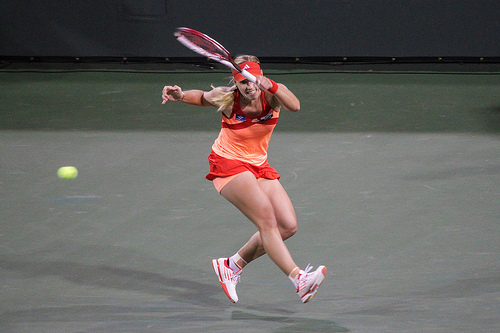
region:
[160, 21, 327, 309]
Woman in red playing tennis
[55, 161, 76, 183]
bright yellow tennis ball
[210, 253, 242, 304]
orange and white tennis shoes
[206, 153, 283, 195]
red and salmon tennis shorts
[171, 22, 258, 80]
red and white tennis racquet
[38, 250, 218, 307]
tennis player casting shadow on the ground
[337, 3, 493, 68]
black riveted game tarp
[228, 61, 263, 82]
red visor with white logo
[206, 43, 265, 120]
woman with long blonde hair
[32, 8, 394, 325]
woman playing an aggressive game of tennis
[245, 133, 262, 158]
the shirt is peach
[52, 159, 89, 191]
the ball is green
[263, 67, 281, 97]
the wristband is red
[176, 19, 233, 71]
she is swinging a racket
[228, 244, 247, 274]
the socks are white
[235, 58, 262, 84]
the visor is red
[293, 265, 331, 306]
the shoe is white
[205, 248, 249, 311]
the shoe has red lines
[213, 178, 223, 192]
the shorts are peach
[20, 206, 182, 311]
The ground is made of concrete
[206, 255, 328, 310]
The feet of the tennis player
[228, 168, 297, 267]
The legs of the tennis player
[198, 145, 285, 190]
The woman is wearing an orange skirt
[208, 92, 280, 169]
The woman is wearing a peach top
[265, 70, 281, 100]
The woman is wearing an orange wrist band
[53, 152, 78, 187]
The tennis ball is green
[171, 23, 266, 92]
The tennis racket is the woman's hand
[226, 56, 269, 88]
The woman is wearing a hat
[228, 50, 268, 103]
The head of the woman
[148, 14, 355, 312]
player on tennis court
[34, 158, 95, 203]
yellow tennis ball in motion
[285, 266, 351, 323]
shoe of the tennis player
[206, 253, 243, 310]
shoe of the tennis player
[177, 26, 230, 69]
racquet in player's hand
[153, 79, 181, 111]
hand of the tennis player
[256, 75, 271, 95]
hand of the tennis player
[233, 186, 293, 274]
leg of the tennis player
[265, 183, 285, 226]
leg of the tennis player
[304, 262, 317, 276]
laces of the tennis shoe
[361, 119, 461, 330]
The ground is made of concrete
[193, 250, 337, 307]
The woman has on shoes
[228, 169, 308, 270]
The legs of the woman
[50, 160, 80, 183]
The ball is the color green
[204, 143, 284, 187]
The skirt is the color orange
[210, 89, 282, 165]
The shirt is the color peach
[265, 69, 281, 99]
The wrist band is the color orange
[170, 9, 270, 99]
The woman is holding a tennis racket